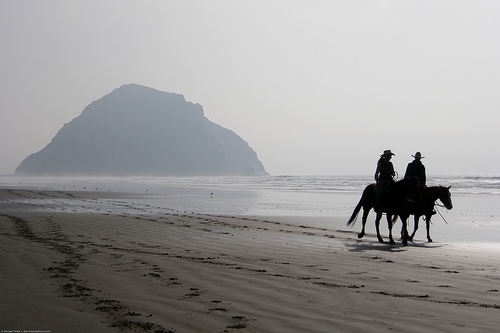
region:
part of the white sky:
[261, 63, 351, 157]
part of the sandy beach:
[128, 189, 248, 299]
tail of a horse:
[348, 203, 359, 225]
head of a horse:
[433, 176, 454, 206]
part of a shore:
[243, 162, 334, 210]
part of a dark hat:
[381, 150, 399, 158]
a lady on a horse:
[371, 142, 400, 185]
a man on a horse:
[398, 145, 433, 200]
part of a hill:
[76, 87, 201, 166]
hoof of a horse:
[349, 229, 369, 241]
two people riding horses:
[344, 131, 443, 206]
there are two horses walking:
[361, 175, 476, 245]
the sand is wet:
[178, 179, 297, 220]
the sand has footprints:
[48, 256, 141, 328]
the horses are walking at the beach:
[359, 152, 456, 238]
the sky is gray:
[268, 76, 320, 113]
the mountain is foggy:
[46, 81, 300, 177]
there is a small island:
[17, 70, 299, 206]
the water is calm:
[231, 170, 305, 195]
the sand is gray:
[249, 270, 358, 322]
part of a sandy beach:
[254, 235, 354, 295]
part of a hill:
[132, 95, 190, 155]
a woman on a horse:
[376, 146, 396, 184]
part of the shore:
[242, 160, 302, 201]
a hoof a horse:
[357, 227, 368, 239]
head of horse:
[438, 178, 451, 223]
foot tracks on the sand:
[141, 253, 218, 317]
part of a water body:
[459, 168, 486, 190]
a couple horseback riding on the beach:
[334, 143, 448, 248]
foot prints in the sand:
[59, 236, 114, 273]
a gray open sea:
[274, 171, 344, 190]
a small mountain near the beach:
[6, 84, 254, 188]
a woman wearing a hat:
[370, 144, 397, 187]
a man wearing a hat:
[406, 154, 435, 189]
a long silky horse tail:
[346, 189, 366, 229]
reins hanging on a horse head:
[435, 201, 455, 223]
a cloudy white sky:
[271, 61, 379, 115]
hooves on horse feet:
[359, 231, 434, 244]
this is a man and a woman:
[345, 150, 452, 237]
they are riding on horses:
[356, 150, 448, 243]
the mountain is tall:
[34, 81, 210, 171]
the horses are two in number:
[353, 189, 448, 234]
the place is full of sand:
[6, 226, 299, 331]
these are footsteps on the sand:
[52, 256, 83, 300]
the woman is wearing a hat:
[381, 150, 394, 155]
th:
[258, 174, 325, 189]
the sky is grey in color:
[2, 1, 498, 79]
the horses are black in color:
[358, 182, 455, 231]